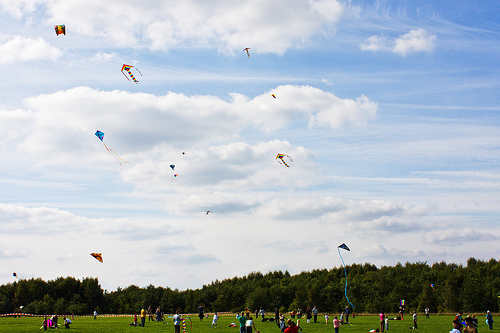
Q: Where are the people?
A: In grass.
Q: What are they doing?
A: Flying kites.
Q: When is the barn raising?
A: No barn.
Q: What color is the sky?
A: Blue.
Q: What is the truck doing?
A: No truck.